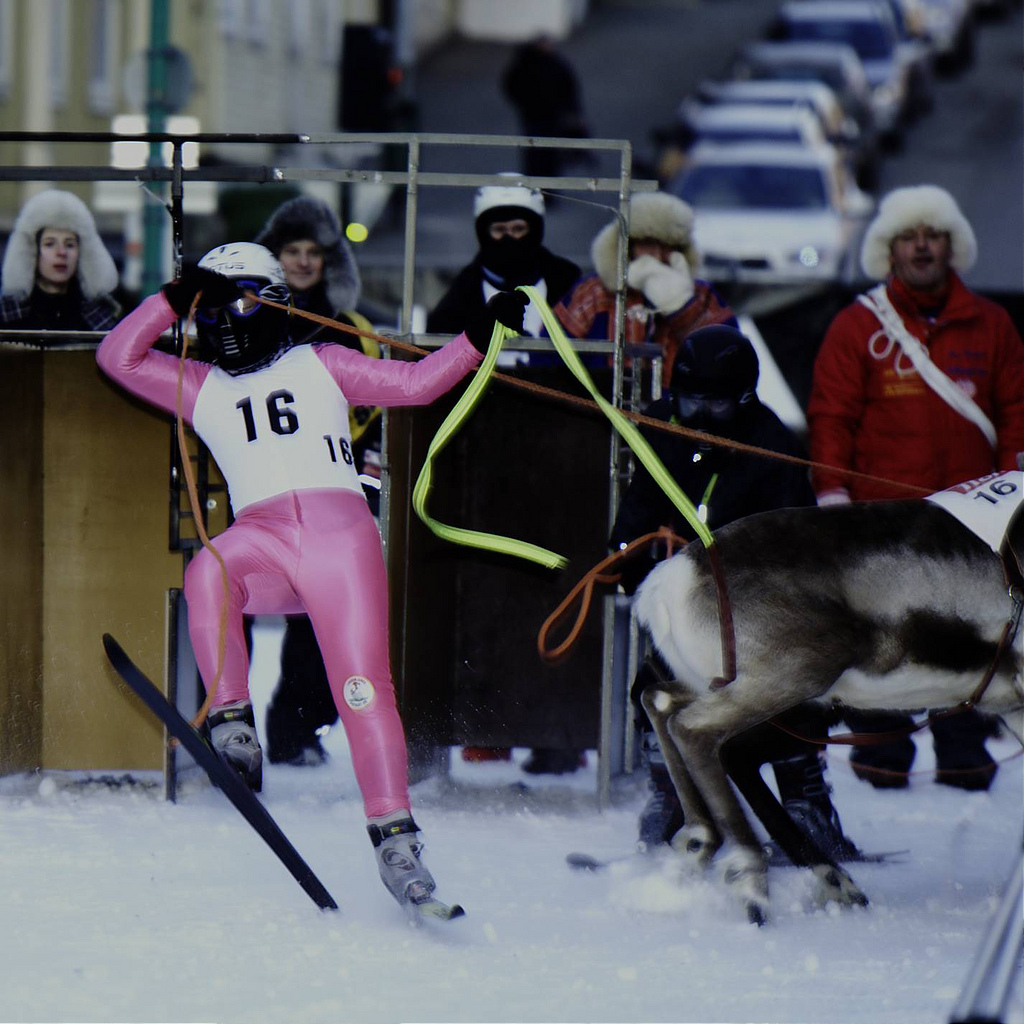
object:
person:
[599, 320, 864, 867]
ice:
[0, 770, 1022, 1024]